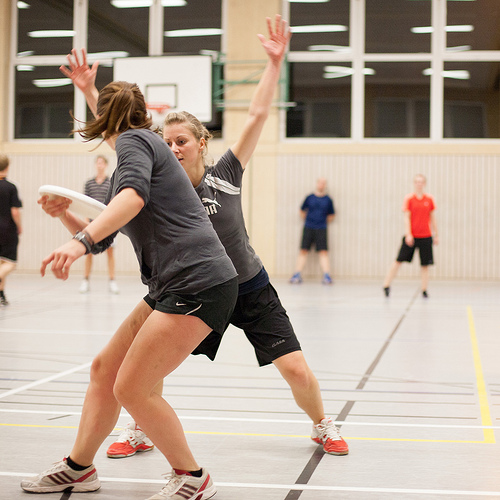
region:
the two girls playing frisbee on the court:
[16, 9, 355, 499]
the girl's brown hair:
[65, 77, 151, 143]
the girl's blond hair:
[159, 107, 212, 150]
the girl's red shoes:
[105, 397, 350, 462]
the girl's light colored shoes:
[13, 456, 220, 496]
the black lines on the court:
[273, 445, 326, 472]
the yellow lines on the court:
[455, 316, 482, 358]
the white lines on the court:
[320, 468, 395, 498]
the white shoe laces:
[312, 420, 344, 445]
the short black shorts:
[137, 264, 240, 338]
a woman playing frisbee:
[16, 80, 191, 392]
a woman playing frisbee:
[132, 154, 300, 487]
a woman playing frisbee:
[54, 71, 251, 483]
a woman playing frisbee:
[179, 169, 225, 374]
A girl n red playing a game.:
[380, 165, 446, 305]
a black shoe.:
[409, 289, 434, 304]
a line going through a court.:
[279, 281, 430, 498]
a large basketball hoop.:
[96, 51, 217, 145]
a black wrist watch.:
[66, 222, 110, 256]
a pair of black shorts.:
[110, 260, 267, 365]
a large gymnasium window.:
[286, 4, 498, 139]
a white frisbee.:
[29, 176, 133, 251]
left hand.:
[36, 242, 93, 292]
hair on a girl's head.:
[149, 101, 215, 136]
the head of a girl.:
[61, 69, 166, 156]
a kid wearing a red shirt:
[371, 171, 445, 302]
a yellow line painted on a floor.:
[456, 293, 498, 450]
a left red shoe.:
[306, 408, 358, 462]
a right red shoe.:
[104, 420, 173, 465]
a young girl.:
[154, 88, 234, 183]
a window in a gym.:
[277, 54, 367, 145]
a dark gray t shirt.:
[96, 121, 263, 296]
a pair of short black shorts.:
[132, 267, 249, 367]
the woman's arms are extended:
[61, 21, 295, 180]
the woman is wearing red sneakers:
[308, 414, 353, 461]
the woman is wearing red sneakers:
[106, 421, 156, 461]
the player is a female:
[102, 23, 352, 460]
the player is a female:
[20, 81, 225, 499]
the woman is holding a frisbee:
[42, 179, 109, 224]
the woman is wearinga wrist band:
[71, 228, 97, 253]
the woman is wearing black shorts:
[142, 273, 243, 330]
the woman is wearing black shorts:
[191, 261, 304, 364]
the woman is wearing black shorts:
[397, 233, 437, 268]